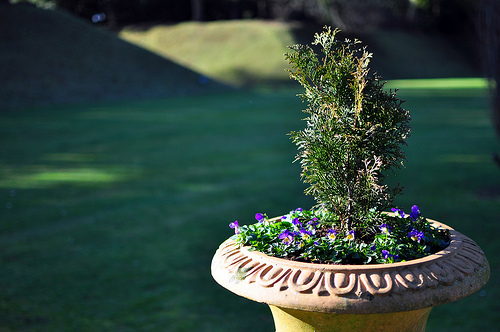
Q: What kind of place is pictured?
A: It is a lawn.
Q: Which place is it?
A: It is a lawn.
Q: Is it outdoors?
A: Yes, it is outdoors.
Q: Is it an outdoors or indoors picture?
A: It is outdoors.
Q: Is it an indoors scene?
A: No, it is outdoors.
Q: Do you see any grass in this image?
A: Yes, there is grass.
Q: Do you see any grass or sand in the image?
A: Yes, there is grass.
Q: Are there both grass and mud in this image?
A: No, there is grass but no mud.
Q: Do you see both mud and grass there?
A: No, there is grass but no mud.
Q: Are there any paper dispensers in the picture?
A: No, there are no paper dispensers.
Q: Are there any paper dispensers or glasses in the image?
A: No, there are no paper dispensers or glasses.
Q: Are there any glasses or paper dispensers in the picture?
A: No, there are no paper dispensers or glasses.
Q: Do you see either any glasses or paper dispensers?
A: No, there are no paper dispensers or glasses.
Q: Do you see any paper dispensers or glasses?
A: No, there are no paper dispensers or glasses.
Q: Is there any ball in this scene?
A: No, there are no balls.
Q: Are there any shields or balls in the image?
A: No, there are no balls or shields.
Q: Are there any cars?
A: No, there are no cars.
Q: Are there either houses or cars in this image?
A: No, there are no cars or houses.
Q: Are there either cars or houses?
A: No, there are no cars or houses.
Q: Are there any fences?
A: No, there are no fences.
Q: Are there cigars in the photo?
A: No, there are no cigars.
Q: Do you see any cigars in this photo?
A: No, there are no cigars.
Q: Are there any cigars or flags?
A: No, there are no cigars or flags.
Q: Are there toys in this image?
A: No, there are no toys.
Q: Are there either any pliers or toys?
A: No, there are no toys or pliers.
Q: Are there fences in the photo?
A: No, there are no fences.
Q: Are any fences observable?
A: No, there are no fences.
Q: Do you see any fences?
A: No, there are no fences.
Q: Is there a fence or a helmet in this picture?
A: No, there are no fences or helmets.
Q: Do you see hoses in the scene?
A: No, there are no hoses.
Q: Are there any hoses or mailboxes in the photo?
A: No, there are no hoses or mailboxes.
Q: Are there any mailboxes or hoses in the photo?
A: No, there are no hoses or mailboxes.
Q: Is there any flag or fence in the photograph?
A: No, there are no fences or flags.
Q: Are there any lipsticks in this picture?
A: No, there are no lipsticks.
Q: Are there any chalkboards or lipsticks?
A: No, there are no lipsticks or chalkboards.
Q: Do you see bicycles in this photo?
A: No, there are no bicycles.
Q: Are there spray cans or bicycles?
A: No, there are no bicycles or spray cans.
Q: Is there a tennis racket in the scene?
A: No, there are no rackets.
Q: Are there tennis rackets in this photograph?
A: No, there are no tennis rackets.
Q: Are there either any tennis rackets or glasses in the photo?
A: No, there are no tennis rackets or glasses.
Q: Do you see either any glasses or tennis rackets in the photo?
A: No, there are no tennis rackets or glasses.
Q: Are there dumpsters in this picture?
A: No, there are no dumpsters.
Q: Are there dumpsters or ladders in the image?
A: No, there are no dumpsters or ladders.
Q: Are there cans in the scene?
A: No, there are no cans.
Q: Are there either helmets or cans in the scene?
A: No, there are no cans or helmets.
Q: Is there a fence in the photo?
A: No, there are no fences.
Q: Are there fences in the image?
A: No, there are no fences.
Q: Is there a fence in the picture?
A: No, there are no fences.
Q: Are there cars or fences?
A: No, there are no fences or cars.